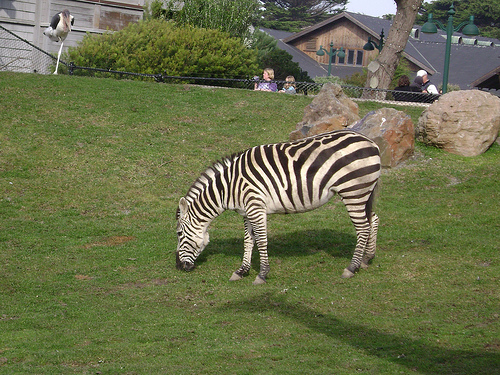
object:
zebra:
[175, 127, 382, 286]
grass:
[0, 68, 498, 374]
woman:
[250, 67, 279, 95]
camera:
[250, 73, 259, 84]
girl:
[280, 73, 298, 96]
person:
[392, 75, 411, 103]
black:
[393, 85, 409, 101]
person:
[412, 76, 429, 103]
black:
[411, 85, 425, 103]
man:
[414, 67, 441, 97]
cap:
[416, 67, 428, 78]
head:
[173, 195, 214, 273]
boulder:
[286, 78, 360, 144]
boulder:
[348, 105, 417, 171]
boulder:
[412, 86, 499, 158]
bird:
[41, 6, 77, 76]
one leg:
[50, 38, 66, 76]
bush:
[53, 18, 254, 90]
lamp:
[420, 1, 482, 94]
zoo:
[1, 0, 499, 373]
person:
[416, 68, 438, 95]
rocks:
[284, 80, 500, 169]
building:
[255, 9, 499, 107]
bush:
[147, 0, 276, 44]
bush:
[261, 47, 313, 89]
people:
[392, 67, 441, 106]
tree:
[360, 1, 426, 100]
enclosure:
[1, 25, 443, 106]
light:
[419, 11, 439, 38]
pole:
[441, 2, 456, 96]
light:
[460, 13, 480, 38]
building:
[3, 0, 185, 76]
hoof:
[253, 274, 265, 285]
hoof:
[227, 270, 243, 280]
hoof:
[339, 265, 354, 279]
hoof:
[359, 260, 370, 271]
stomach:
[266, 168, 334, 220]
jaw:
[181, 219, 208, 248]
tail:
[363, 183, 375, 228]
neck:
[188, 156, 236, 226]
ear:
[177, 194, 189, 219]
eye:
[176, 228, 182, 237]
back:
[252, 127, 351, 159]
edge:
[0, 15, 14, 72]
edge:
[427, 88, 439, 106]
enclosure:
[1, 26, 500, 373]